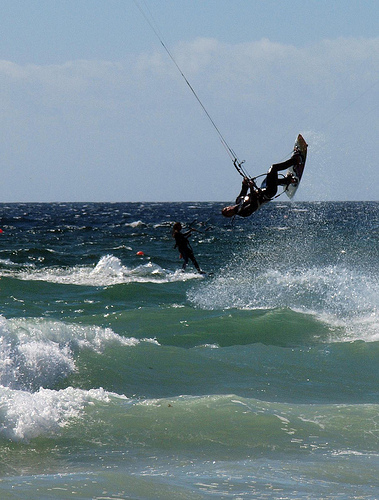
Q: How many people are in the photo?
A: Two.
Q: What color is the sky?
A: Light Blue.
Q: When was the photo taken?
A: Daytime.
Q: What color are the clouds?
A: White.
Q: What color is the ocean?
A: Green.